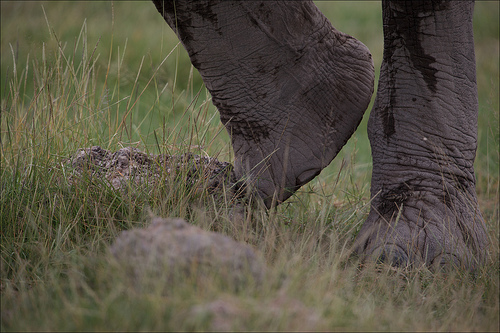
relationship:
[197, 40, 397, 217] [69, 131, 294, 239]
foot with rock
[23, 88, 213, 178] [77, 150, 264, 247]
grass over rock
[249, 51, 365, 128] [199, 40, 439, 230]
wrinkles on foot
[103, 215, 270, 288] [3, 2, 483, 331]
rock on field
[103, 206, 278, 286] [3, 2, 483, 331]
rock in field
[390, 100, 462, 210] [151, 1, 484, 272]
skin in elephant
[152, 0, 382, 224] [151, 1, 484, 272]
leg of elephant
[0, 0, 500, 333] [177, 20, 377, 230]
grass under foot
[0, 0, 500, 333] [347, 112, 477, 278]
grass under foot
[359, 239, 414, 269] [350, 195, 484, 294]
toe nail on foot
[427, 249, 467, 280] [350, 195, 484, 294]
toe nail on foot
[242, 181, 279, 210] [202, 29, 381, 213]
toe nail on foot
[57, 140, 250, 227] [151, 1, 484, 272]
mound kicked by elephant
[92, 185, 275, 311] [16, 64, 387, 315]
mounds amidst fields